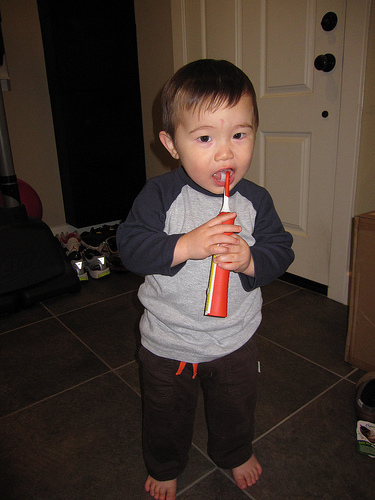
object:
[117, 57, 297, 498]
toddler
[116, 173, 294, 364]
shirt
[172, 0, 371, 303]
door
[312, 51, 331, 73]
knob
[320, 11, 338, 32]
lock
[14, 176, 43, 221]
ball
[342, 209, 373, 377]
box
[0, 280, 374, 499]
floor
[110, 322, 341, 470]
tile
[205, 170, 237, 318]
toothbrush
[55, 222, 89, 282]
shoes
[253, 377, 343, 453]
grout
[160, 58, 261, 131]
hair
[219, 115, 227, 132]
scar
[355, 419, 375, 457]
magazine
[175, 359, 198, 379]
strings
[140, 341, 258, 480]
pants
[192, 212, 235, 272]
hands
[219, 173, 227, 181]
bristles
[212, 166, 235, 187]
mouth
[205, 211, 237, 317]
handle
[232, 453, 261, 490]
foot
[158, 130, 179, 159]
ear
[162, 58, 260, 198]
head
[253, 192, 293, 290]
arm